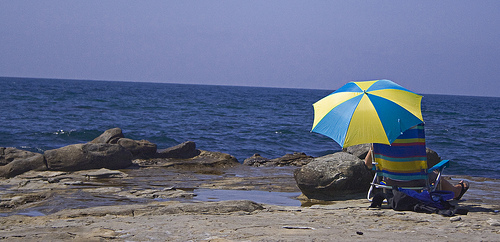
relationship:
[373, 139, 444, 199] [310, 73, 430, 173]
man holding umbrella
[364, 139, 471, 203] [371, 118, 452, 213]
man sitting in a chair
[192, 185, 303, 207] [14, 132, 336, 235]
water on shore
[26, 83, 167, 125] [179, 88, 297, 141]
waves in water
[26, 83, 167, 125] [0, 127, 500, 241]
waves washing shore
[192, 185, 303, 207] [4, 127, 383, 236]
water in rocky area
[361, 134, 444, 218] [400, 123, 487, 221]
chair with person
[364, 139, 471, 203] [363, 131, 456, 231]
man in chair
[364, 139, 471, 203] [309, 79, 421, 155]
man under umbrella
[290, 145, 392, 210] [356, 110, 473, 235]
boulder by chair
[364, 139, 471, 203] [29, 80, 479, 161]
man by ocean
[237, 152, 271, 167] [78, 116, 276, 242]
rock on ground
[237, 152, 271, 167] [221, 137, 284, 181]
rock on ground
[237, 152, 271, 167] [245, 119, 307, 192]
rock on ground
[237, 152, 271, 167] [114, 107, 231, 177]
rock on ground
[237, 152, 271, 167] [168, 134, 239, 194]
rock on ground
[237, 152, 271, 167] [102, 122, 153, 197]
rock on ground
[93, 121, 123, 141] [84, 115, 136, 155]
rock on ground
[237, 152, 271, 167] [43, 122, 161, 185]
rock on ground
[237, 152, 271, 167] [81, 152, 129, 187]
rock on ground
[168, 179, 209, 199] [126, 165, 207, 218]
rock on ground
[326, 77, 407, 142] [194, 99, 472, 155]
umbrella in background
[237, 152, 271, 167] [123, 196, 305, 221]
rock on ground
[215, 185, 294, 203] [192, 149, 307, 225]
water on ground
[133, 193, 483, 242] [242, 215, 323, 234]
sand on ground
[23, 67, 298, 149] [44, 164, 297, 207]
ocean in background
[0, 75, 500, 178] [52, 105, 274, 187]
ocean in ocean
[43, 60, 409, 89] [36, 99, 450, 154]
sky in background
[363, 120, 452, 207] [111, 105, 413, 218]
chair at beach